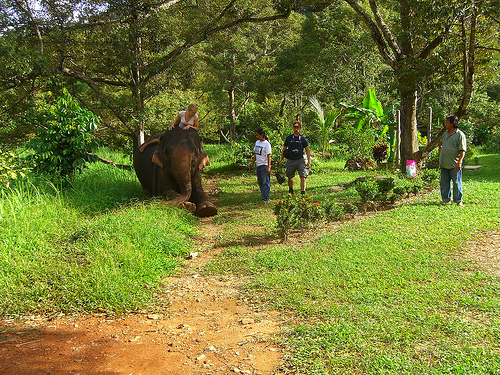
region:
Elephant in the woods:
[141, 133, 245, 198]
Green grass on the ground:
[236, 251, 443, 358]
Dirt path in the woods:
[158, 213, 250, 367]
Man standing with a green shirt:
[433, 113, 486, 220]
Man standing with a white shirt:
[248, 131, 277, 185]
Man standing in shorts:
[283, 119, 318, 185]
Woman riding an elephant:
[133, 97, 243, 216]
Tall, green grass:
[12, 173, 181, 272]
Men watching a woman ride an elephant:
[231, 114, 342, 196]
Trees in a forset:
[13, 66, 179, 188]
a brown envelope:
[132, 124, 240, 216]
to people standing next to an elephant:
[127, 113, 323, 220]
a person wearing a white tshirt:
[247, 126, 273, 169]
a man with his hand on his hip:
[425, 112, 467, 159]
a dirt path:
[116, 206, 273, 358]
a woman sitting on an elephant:
[140, 98, 231, 172]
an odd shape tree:
[358, 5, 486, 168]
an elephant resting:
[111, 90, 223, 217]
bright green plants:
[324, 85, 389, 146]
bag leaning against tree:
[398, 140, 418, 185]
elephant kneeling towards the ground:
[130, 121, 225, 217]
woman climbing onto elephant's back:
[131, 95, 201, 150]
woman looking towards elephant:
[188, 121, 274, 209]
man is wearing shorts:
[280, 155, 312, 181]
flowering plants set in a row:
[272, 170, 433, 240]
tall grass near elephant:
[15, 180, 181, 285]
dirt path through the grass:
[152, 208, 290, 373]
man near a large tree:
[390, 53, 472, 205]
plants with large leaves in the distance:
[302, 76, 385, 166]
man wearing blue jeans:
[434, 163, 473, 200]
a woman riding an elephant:
[135, 100, 216, 217]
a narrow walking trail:
[7, 180, 279, 370]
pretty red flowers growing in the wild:
[273, 192, 322, 237]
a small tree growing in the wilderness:
[24, 91, 114, 180]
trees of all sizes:
[39, 4, 477, 189]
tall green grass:
[6, 161, 125, 210]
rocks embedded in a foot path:
[156, 280, 249, 372]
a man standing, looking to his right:
[436, 114, 466, 211]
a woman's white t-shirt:
[251, 142, 272, 165]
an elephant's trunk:
[164, 152, 192, 207]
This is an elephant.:
[117, 124, 224, 264]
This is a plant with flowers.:
[270, 193, 327, 250]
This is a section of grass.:
[65, 246, 136, 311]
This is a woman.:
[246, 120, 273, 204]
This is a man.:
[421, 95, 472, 217]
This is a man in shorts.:
[273, 117, 318, 195]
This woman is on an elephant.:
[141, 96, 220, 169]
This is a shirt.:
[277, 132, 307, 164]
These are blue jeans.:
[428, 157, 472, 209]